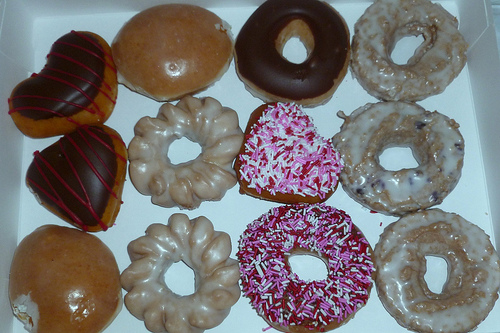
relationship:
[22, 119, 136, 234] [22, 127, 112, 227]
doughnut with glaze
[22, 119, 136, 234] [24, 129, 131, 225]
doughnut with drizzle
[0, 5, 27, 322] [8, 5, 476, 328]
edge of a box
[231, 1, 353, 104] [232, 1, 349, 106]
chocolate on doughnut